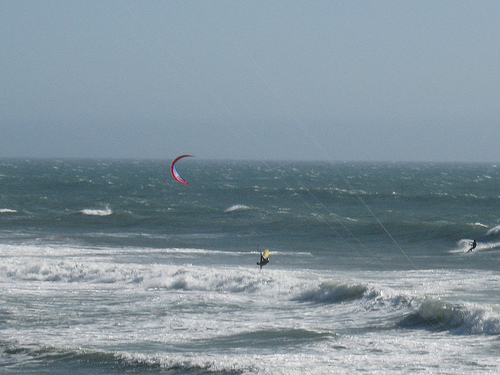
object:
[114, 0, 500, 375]
string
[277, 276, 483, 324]
waves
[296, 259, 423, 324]
wave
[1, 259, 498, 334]
wave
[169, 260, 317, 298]
waves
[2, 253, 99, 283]
waves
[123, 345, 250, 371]
waves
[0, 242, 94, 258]
waves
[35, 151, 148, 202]
white caps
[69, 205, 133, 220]
wave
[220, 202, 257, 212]
wave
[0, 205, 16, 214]
wave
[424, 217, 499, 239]
wave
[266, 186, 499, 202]
wave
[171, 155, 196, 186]
kite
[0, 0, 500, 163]
sky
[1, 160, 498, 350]
water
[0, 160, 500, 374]
ocean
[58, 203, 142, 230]
wave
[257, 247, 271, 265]
person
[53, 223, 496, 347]
waves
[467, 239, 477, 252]
person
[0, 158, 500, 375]
water